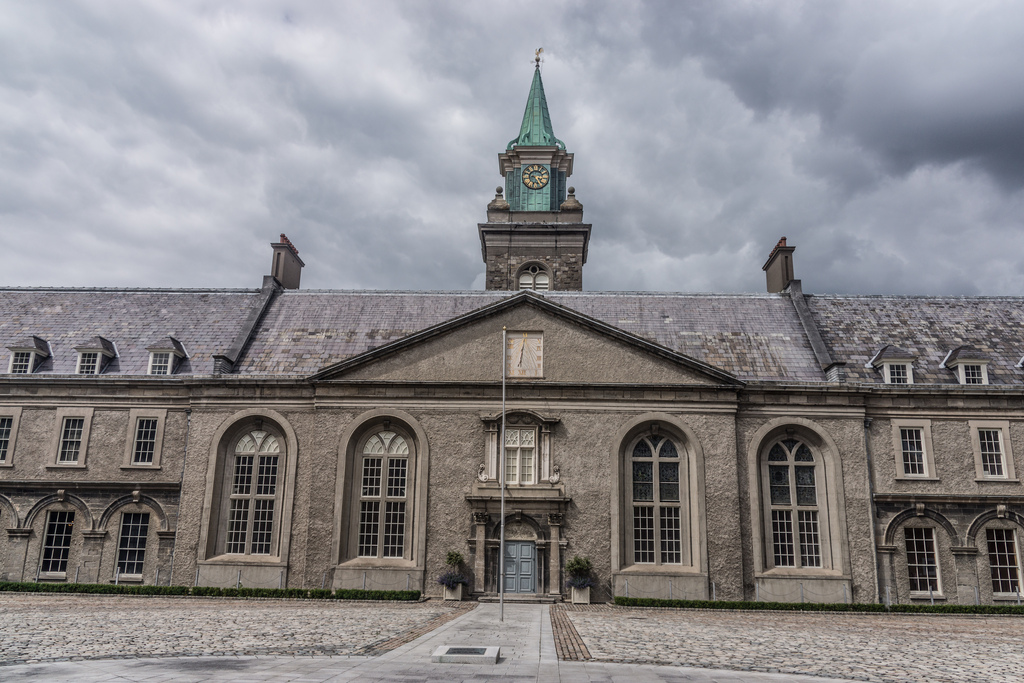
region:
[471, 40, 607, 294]
a steeple on the building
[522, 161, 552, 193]
a clock on the steeple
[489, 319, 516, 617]
a tall pole in front of the building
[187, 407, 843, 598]
four tall arched windows on the building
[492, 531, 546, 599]
a door to the building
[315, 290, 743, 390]
a peaked roof above the doorway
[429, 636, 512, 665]
a square cement with plaque on the ground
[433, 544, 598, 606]
two planters by the doorway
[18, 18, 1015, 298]
gray clouds in the sky above the building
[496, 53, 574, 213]
the green part of the steeple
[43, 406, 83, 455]
a window on a building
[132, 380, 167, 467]
a window on a building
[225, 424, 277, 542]
a window on a building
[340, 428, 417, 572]
a window on a building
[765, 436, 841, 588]
a window on a building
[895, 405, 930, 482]
a window on a building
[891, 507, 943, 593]
a window on a building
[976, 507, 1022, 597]
a window on a building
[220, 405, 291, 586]
window on a church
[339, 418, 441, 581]
window on a church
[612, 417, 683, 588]
window on a church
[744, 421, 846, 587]
window on a church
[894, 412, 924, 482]
window on a church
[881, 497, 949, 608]
window on a church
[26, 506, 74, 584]
window on a church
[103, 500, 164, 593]
window on a church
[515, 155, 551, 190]
clock on top of the tower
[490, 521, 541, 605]
gray door on the building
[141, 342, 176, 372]
window on the building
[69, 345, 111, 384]
window on the building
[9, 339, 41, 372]
window on the building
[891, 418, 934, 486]
window on the building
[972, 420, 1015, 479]
window on the building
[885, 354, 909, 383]
window on the building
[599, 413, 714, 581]
window on the building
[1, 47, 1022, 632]
large long stone building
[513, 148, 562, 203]
clock in green steeple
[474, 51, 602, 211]
green colored steeple on stone building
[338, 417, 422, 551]
large window in stone building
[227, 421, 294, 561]
large window in stone building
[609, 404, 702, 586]
large window in stone building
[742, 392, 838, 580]
large window in stone building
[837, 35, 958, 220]
gray and white clouds in sky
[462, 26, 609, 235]
a clock on a tower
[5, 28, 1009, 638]
a large historical building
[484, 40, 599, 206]
a green tower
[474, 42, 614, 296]
steeple on top of building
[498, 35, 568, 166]
green top on steeple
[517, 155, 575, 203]
round clock on steeple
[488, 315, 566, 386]
square clock on front of building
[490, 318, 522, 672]
pole in front of building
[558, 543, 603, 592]
green plant in pot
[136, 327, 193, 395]
small window on top of building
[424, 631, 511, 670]
concrete drain in sidewalk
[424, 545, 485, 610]
concrete pot with green plant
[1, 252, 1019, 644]
large building with many windows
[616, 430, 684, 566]
A window on a building.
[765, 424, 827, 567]
A window on a building.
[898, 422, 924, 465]
A window on a building.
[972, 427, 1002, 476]
A window on a building.